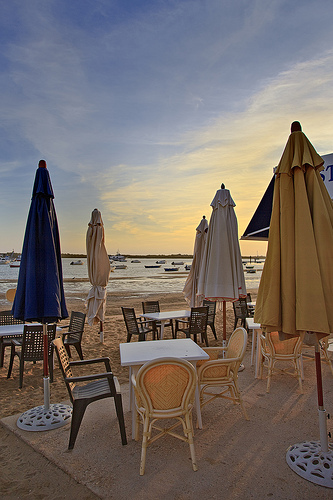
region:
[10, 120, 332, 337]
The umbrellas are closed.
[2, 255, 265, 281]
Boats are in the harbor.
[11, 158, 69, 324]
The umbrella is dark blue.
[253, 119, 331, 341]
The umbrella is yellow.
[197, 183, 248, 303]
The umbrella is white.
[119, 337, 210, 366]
The table is white.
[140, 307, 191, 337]
The table is white.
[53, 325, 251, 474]
Three chairs surround the table.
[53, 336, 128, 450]
The chair is dark brown.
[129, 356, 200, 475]
The chair is a very light tan.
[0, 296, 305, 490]
Tables and chairs at the beach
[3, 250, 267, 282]
Boats on the water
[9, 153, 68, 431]
Closed blue umbrella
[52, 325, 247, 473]
Table and three chairs on the patio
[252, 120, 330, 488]
Folded yellow umbrella on patio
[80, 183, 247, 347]
Folded umbrellas by the beach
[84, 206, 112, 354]
Umbrella in the sand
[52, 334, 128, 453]
Brown chair at the table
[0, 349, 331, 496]
Patio in the sand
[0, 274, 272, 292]
Stretch of water near the sand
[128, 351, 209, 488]
chair next to table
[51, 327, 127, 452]
chair next to table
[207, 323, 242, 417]
chair next to table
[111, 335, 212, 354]
table next to chairs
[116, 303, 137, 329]
chair next to table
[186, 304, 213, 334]
chair next to table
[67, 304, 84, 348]
chair next to table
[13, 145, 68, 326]
umbrella next to chair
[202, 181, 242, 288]
tent next to table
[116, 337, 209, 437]
a square patio table bear the beach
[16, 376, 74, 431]
a metal stand on the ground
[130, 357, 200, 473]
a light brown wooden chair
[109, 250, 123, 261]
a boat on the water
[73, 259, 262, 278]
small boats on the water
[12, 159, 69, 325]
a blue umbrella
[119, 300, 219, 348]
a white table with four brown chairs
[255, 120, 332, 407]
a yellow umbrella on a red pole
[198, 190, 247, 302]
a beige umbrella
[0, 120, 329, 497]
tables and umbrellas near a beach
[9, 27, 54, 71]
white clouds in blue sky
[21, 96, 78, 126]
white clouds in blue sky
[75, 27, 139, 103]
white clouds in blue sky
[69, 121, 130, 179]
white clouds in blue sky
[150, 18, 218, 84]
white clouds in blue sky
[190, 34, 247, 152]
white clouds in blue sky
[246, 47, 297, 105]
white clouds in blue sky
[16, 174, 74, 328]
closed tent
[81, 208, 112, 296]
closed brown tent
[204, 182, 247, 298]
closed brown tent